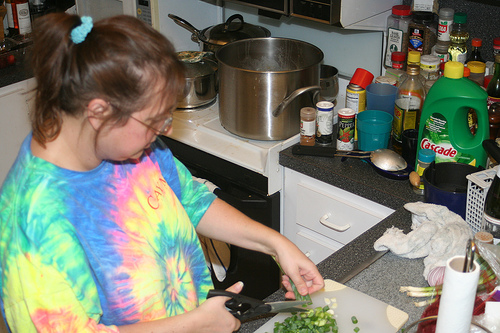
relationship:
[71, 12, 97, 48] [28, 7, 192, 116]
scrunchie holds hair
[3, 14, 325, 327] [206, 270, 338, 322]
woman holds scissors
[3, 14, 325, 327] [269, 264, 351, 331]
woman prepares food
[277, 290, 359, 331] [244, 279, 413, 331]
vegetables on cutting board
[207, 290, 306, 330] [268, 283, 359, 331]
scissors cut food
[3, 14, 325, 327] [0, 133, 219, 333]
woman wearing a shirt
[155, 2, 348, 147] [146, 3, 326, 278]
pots on stove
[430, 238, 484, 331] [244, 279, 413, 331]
paper towel/holder in front of cutting board